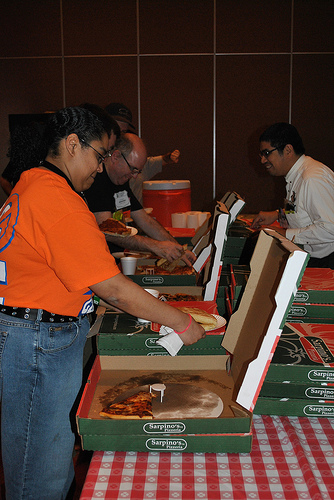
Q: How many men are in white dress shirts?
A: 1.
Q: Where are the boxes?
A: On a table.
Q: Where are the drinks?
A: Far end of table.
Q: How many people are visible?
A: 5.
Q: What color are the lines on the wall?
A: Silver.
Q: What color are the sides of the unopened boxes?
A: Green.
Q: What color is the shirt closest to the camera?
A: Orange.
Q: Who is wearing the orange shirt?
A: Lady.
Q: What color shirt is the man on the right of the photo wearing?
A: White.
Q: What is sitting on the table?
A: Pizza boxes.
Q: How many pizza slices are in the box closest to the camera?
A: One.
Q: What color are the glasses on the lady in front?
A: Black.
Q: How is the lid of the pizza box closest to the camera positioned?
A: Open.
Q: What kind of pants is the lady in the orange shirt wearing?
A: Jeans.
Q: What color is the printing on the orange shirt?
A: Blue.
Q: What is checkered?
A: Tablecloth.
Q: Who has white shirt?
A: Man in glasses.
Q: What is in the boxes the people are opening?
A: Pizza.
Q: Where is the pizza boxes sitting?
A: On a table.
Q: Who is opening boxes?
A: The people.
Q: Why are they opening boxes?
A: To get pizza.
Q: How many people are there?
A: Four.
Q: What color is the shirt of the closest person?
A: Orange.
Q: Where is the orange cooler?
A: Far end of table.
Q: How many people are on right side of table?
A: One.